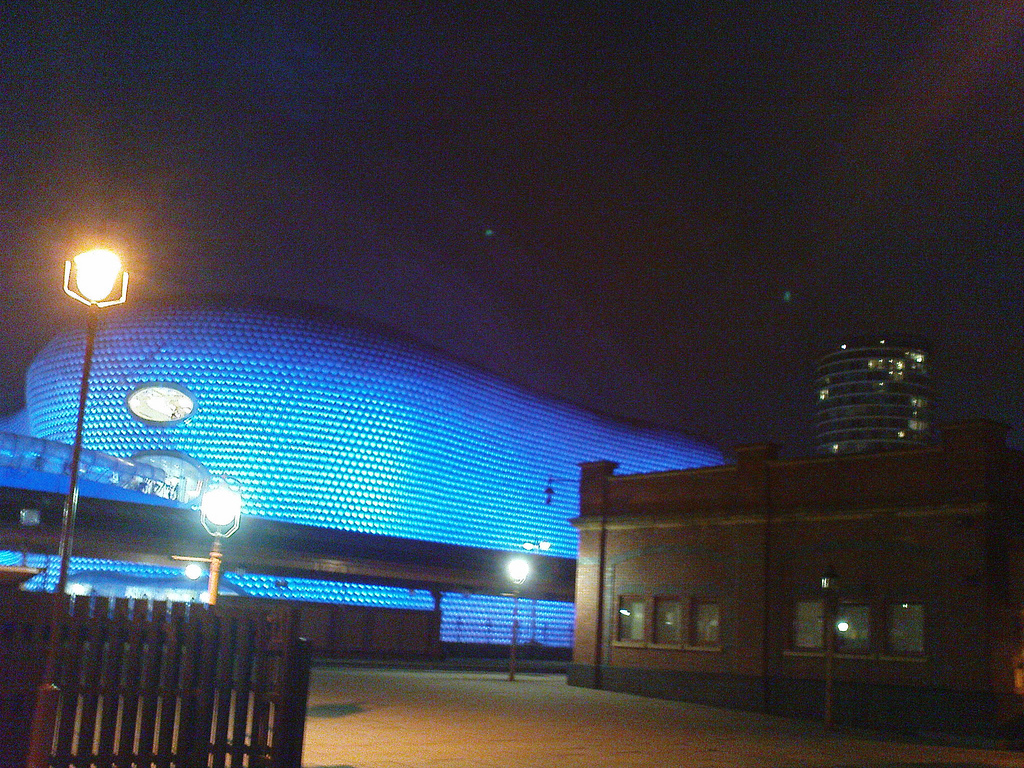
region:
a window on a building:
[649, 601, 676, 653]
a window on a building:
[682, 594, 724, 643]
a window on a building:
[789, 601, 835, 652]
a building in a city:
[578, 442, 1021, 749]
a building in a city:
[19, 300, 753, 668]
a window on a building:
[131, 579, 155, 602]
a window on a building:
[160, 586, 202, 603]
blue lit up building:
[35, 307, 718, 688]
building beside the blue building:
[560, 409, 1022, 730]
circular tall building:
[815, 330, 927, 449]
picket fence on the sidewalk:
[12, 573, 301, 764]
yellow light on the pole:
[53, 216, 151, 602]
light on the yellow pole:
[198, 480, 250, 598]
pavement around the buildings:
[272, 654, 1018, 760]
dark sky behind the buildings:
[4, 10, 1020, 479]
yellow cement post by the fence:
[26, 683, 62, 766]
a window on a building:
[656, 594, 680, 651]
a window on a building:
[777, 588, 828, 645]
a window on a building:
[831, 592, 861, 656]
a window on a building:
[875, 592, 926, 657]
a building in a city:
[589, 440, 1005, 750]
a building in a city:
[798, 329, 942, 454]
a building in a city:
[0, 286, 741, 686]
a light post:
[41, 241, 128, 565]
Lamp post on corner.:
[474, 539, 577, 677]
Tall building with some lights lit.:
[808, 317, 930, 450]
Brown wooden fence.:
[9, 595, 314, 763]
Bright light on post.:
[188, 484, 255, 602]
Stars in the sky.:
[454, 204, 806, 329]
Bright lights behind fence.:
[19, 234, 317, 757]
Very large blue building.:
[8, 294, 718, 658]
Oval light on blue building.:
[116, 377, 205, 438]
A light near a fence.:
[49, 219, 136, 602]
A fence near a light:
[3, 566, 317, 764]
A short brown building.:
[568, 421, 1020, 744]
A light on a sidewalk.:
[192, 482, 247, 607]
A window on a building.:
[612, 586, 650, 647]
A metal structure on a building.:
[0, 484, 576, 606]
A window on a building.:
[834, 598, 874, 655]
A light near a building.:
[504, 551, 531, 685]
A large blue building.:
[0, 297, 746, 671]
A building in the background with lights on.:
[796, 295, 959, 457]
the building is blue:
[345, 420, 464, 515]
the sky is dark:
[517, 180, 609, 232]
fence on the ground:
[147, 614, 322, 764]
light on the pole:
[54, 250, 121, 309]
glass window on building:
[620, 593, 643, 639]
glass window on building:
[650, 594, 680, 636]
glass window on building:
[689, 593, 719, 645]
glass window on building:
[790, 597, 820, 652]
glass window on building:
[834, 600, 872, 654]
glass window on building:
[884, 597, 917, 655]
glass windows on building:
[613, 593, 683, 652]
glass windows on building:
[784, 591, 864, 646]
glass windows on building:
[620, 598, 716, 649]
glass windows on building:
[789, 597, 925, 662]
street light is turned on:
[65, 248, 135, 306]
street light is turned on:
[198, 481, 241, 538]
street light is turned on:
[497, 554, 536, 586]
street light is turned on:
[523, 534, 552, 554]